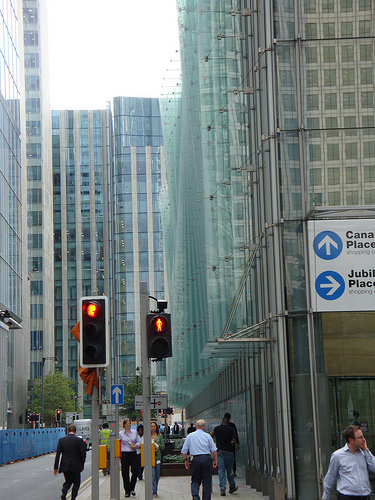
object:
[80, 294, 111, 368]
light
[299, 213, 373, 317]
sign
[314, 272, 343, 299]
arrow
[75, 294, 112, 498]
pole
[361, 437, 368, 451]
hand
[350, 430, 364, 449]
face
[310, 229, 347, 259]
circle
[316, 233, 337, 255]
arrow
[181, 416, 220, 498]
man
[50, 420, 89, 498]
man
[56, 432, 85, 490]
suit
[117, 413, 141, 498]
woman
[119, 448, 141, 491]
pants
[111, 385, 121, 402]
arrow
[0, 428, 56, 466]
barrier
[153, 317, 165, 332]
light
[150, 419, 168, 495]
woman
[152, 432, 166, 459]
shirt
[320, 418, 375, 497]
man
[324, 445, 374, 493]
shirt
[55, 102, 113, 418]
building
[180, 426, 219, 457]
shirt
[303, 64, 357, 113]
building windows